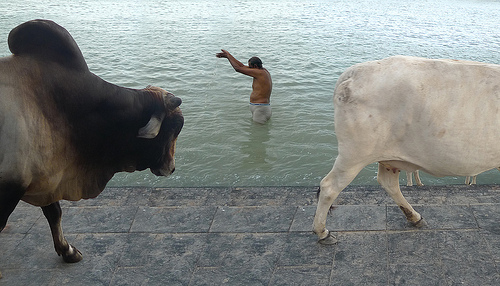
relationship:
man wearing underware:
[208, 40, 292, 170] [234, 88, 292, 133]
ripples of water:
[208, 131, 275, 184] [305, 4, 385, 51]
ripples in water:
[172, 65, 204, 86] [5, 0, 487, 189]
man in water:
[213, 49, 273, 124] [171, 21, 356, 148]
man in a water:
[213, 49, 273, 124] [171, 128, 248, 165]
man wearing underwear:
[213, 49, 273, 124] [251, 99, 273, 126]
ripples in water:
[277, 36, 317, 95] [5, 0, 487, 189]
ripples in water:
[257, 140, 337, 167] [5, 0, 487, 189]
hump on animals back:
[6, 19, 79, 78] [2, 24, 127, 129]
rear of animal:
[326, 49, 446, 181] [292, 47, 499, 246]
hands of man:
[212, 45, 231, 61] [209, 35, 281, 127]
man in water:
[213, 49, 273, 124] [5, 0, 487, 189]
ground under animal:
[0, 185, 497, 284] [2, 18, 182, 264]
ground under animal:
[0, 185, 497, 284] [309, 52, 498, 252]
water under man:
[5, 0, 487, 189] [213, 48, 277, 134]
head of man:
[247, 56, 263, 69] [215, 49, 270, 124]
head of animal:
[127, 86, 181, 177] [2, 18, 182, 264]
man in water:
[213, 49, 273, 124] [255, 5, 497, 66]